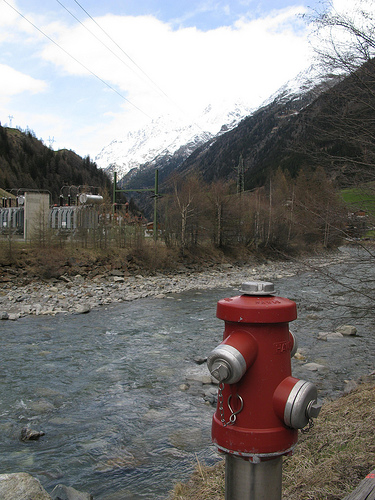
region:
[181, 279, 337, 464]
a red fire hydrant next to a greek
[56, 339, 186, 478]
clear flowing water of the creek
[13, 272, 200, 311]
many rocks next to the creek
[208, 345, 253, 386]
grey metal cap of the fire hydrant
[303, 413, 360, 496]
brown grass of the grand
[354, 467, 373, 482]
red lines on a piece of wood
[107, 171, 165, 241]
green metal posts behind the creek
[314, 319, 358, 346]
a large rock sticking out of the water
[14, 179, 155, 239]
a power station next to the creek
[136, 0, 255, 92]
cloudy blue skies over the scene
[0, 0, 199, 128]
Electrical lines leading to the power plant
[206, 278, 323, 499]
Red and silver fire hydrant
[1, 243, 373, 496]
Swiftly flowing stream of clear water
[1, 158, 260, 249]
Electrical transformers at a power plant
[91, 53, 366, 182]
Snow covered mountain top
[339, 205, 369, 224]
Red and white wooden house in the background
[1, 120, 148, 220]
Tree covered hillside with electrical posts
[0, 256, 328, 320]
Medium sized rocks on the stream shore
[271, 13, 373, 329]
Bare tree branches near the hydrant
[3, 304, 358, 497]
Rocks protruding from the water stream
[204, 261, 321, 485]
Fire hydrant next to the creek.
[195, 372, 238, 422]
Chain haning from fire hydrant.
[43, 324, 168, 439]
Water in the creek.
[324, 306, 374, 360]
Big rocks in the water.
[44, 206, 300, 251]
A gate on the side of the water.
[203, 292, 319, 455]
The fire hydrant is red and grey.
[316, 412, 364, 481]
The grass is dry and brown.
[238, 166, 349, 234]
Weed and branches covering the fence.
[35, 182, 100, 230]
A building behind the fence.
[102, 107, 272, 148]
Snow on top of the mountain.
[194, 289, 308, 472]
a red fire hydrant next to a creek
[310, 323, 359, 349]
large rocks sticking out of the water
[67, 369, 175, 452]
clear flowing water of the creek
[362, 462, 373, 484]
red lines on a piece of wood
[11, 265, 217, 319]
many rocks lined on the shore of the creek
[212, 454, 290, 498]
grey metal post of the fire hydrant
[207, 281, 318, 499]
A metal fire hydrant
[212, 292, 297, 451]
The hydrant is red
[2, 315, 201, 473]
Water is running in a stream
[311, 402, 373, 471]
The grass is dead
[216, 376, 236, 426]
A chain on the hydrant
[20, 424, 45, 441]
Rock sticking out of the water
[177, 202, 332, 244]
The trees are dead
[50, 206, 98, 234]
Building in the background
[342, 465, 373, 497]
Pieces of wood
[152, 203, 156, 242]
A green metal post